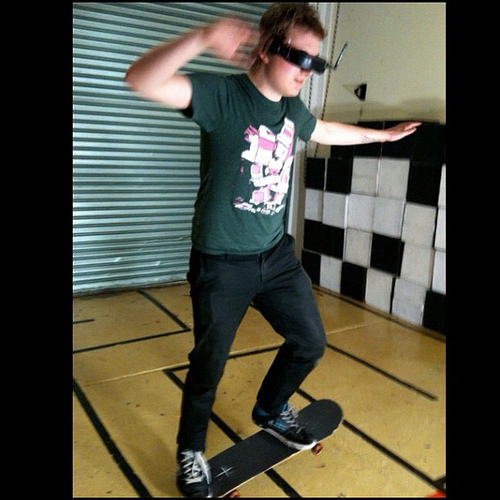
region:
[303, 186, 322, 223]
white square on wall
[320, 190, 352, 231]
white square on wall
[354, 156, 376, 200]
white square on wall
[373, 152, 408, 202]
white square on wall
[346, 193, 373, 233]
white square on wall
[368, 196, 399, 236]
white square on wall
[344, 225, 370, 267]
white square on wall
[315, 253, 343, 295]
white square on wall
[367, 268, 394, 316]
white square on wall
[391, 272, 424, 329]
white square on wall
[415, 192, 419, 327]
Black and white tiles on the wall.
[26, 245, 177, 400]
.Black and white tiles on the wall.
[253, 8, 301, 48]
Black and white tiles on the wall.